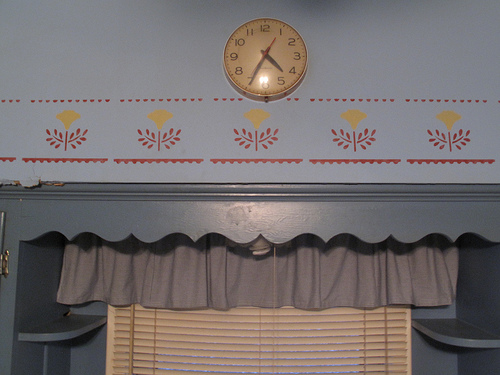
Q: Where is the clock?
A: The wall.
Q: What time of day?
A: Daytime.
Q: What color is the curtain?
A: Dark Grey.